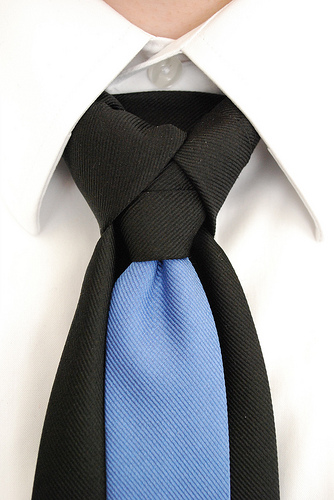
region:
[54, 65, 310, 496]
a closeup picture of a tie.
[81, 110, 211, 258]
The tie has a complex knot.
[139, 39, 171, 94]
A button above the tie.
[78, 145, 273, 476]
The tie is black and blue.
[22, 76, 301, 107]
The shirt is white.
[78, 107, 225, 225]
The knot is black.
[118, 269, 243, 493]
Blue material within the tie.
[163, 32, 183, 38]
The skin is exposed.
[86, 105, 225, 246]
The tie is made of cotton.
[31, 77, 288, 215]
Part of the collar covers the tie.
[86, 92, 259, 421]
a black and blue tie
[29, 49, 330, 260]
a shirt with collar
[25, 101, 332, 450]
a shirt with collar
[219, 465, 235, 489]
edge of a tie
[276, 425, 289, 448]
part of a shirt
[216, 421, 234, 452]
edge of a tie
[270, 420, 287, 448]
part of a shirt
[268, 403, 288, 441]
part of a short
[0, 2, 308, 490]
the man is wearing a tie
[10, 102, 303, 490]
the tie is black and blue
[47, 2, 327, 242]
the shirt is white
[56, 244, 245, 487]
the middle of the tie is blue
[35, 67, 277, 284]
the tie is in a knot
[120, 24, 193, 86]
the button is fastened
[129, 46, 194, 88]
the button is white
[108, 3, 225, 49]
the man`s race is white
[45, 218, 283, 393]
the cloth on the tie has lines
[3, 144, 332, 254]
the collar is pointy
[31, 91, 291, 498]
the black base of a mans necktie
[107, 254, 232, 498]
the blue top portion of a necktie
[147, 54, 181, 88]
an opal like button on a collar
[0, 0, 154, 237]
a portion of a collar on a shirt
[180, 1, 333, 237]
a portion of a collar on a shirt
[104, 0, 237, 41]
a mans neck in a collar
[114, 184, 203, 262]
a loop on a necktie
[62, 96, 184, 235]
a loop on a necktie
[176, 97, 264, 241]
a loop on a necktie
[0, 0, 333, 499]
a white dress shirt